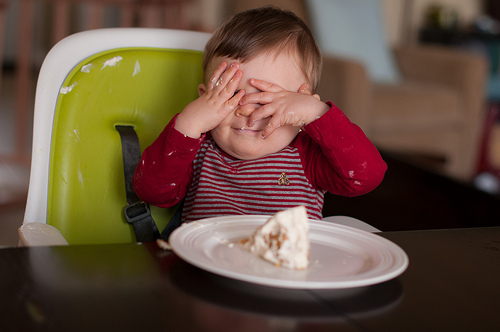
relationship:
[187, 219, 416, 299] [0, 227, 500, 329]
plate on table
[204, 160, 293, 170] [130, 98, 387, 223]
stripe on shirt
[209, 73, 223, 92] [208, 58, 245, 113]
food on fingers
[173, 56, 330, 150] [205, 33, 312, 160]
hands on face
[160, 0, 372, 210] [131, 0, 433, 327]
baby covering their eyes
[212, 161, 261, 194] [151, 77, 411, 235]
strip on shirt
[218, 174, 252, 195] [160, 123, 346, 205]
red strip on shirt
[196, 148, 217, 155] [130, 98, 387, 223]
stripe on shirt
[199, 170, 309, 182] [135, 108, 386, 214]
stripe on shirt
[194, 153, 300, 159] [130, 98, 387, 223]
stripe on shirt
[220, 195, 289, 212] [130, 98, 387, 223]
red stripe on shirt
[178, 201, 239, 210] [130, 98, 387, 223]
stripe on shirt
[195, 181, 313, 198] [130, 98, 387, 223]
stripe on shirt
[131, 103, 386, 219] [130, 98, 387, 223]
red stripe on shirt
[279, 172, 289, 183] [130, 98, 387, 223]
bear on shirt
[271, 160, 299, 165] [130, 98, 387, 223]
red stripe on shirt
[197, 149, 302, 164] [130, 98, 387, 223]
red stripe on shirt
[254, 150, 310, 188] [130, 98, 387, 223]
strip on shirt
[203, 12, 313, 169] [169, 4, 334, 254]
head of baby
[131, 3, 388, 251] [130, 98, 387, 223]
baby wearing shirt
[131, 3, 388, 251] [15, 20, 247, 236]
baby sitting in chair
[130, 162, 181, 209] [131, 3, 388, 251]
elbow of baby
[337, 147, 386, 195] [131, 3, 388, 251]
elbow of baby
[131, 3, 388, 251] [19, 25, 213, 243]
baby sitting in highchair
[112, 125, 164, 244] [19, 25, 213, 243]
black strap on highchair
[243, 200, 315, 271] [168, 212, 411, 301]
food on plate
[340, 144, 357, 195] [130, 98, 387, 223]
food stain on shirt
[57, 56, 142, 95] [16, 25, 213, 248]
food smeared on highchair